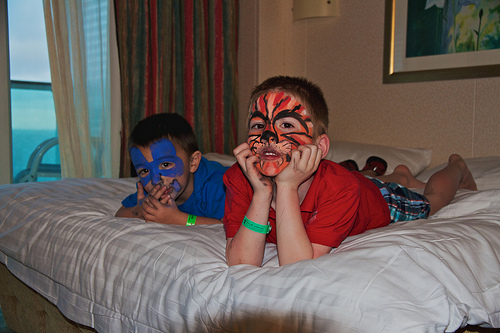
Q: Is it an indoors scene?
A: Yes, it is indoors.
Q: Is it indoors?
A: Yes, it is indoors.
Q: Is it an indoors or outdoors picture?
A: It is indoors.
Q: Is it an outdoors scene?
A: No, it is indoors.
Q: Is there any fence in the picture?
A: No, there are no fences.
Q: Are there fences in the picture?
A: No, there are no fences.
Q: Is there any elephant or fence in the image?
A: No, there are no fences or elephants.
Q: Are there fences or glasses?
A: No, there are no fences or glasses.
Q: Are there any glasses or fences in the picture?
A: No, there are no fences or glasses.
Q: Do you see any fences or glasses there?
A: No, there are no fences or glasses.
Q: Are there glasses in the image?
A: No, there are no glasses.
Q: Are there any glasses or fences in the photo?
A: No, there are no glasses or fences.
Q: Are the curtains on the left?
A: Yes, the curtains are on the left of the image.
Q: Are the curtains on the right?
A: No, the curtains are on the left of the image.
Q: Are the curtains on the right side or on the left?
A: The curtains are on the left of the image.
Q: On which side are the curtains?
A: The curtains are on the left of the image.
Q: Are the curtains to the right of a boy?
A: No, the curtains are to the left of a boy.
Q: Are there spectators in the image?
A: No, there are no spectators.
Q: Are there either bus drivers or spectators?
A: No, there are no spectators or bus drivers.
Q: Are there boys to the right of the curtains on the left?
A: Yes, there is a boy to the right of the curtains.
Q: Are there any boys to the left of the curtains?
A: No, the boy is to the right of the curtains.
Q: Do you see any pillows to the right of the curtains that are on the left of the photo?
A: No, there is a boy to the right of the curtains.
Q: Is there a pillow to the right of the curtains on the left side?
A: No, there is a boy to the right of the curtains.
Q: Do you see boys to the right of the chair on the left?
A: Yes, there is a boy to the right of the chair.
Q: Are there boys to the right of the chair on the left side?
A: Yes, there is a boy to the right of the chair.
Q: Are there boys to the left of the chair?
A: No, the boy is to the right of the chair.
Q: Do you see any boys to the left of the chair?
A: No, the boy is to the right of the chair.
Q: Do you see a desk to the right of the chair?
A: No, there is a boy to the right of the chair.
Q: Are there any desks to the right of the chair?
A: No, there is a boy to the right of the chair.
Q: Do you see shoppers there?
A: No, there are no shoppers.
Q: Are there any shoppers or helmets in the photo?
A: No, there are no shoppers or helmets.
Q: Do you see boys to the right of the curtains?
A: Yes, there is a boy to the right of the curtains.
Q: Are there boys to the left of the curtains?
A: No, the boy is to the right of the curtains.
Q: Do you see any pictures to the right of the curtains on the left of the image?
A: No, there is a boy to the right of the curtains.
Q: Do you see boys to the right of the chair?
A: Yes, there is a boy to the right of the chair.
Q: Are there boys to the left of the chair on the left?
A: No, the boy is to the right of the chair.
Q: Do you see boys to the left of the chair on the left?
A: No, the boy is to the right of the chair.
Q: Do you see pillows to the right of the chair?
A: No, there is a boy to the right of the chair.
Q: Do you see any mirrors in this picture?
A: No, there are no mirrors.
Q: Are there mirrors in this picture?
A: No, there are no mirrors.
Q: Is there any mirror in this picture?
A: No, there are no mirrors.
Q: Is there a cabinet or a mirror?
A: No, there are no mirrors or cabinets.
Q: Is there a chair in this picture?
A: Yes, there is a chair.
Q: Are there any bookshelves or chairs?
A: Yes, there is a chair.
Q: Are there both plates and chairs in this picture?
A: No, there is a chair but no plates.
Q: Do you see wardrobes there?
A: No, there are no wardrobes.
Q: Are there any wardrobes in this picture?
A: No, there are no wardrobes.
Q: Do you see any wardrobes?
A: No, there are no wardrobes.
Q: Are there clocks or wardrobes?
A: No, there are no wardrobes or clocks.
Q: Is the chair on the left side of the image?
A: Yes, the chair is on the left of the image.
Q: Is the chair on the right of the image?
A: No, the chair is on the left of the image.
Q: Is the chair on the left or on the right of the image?
A: The chair is on the left of the image.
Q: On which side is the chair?
A: The chair is on the left of the image.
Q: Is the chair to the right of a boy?
A: No, the chair is to the left of a boy.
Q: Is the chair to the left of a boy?
A: Yes, the chair is to the left of a boy.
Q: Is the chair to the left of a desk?
A: No, the chair is to the left of a boy.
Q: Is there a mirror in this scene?
A: No, there are no mirrors.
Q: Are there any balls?
A: No, there are no balls.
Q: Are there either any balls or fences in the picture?
A: No, there are no balls or fences.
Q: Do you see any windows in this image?
A: Yes, there is a window.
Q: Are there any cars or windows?
A: Yes, there is a window.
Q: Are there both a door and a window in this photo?
A: No, there is a window but no doors.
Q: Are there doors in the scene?
A: No, there are no doors.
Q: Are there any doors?
A: No, there are no doors.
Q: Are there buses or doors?
A: No, there are no doors or buses.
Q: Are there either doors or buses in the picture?
A: No, there are no doors or buses.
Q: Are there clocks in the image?
A: No, there are no clocks.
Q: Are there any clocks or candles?
A: No, there are no clocks or candles.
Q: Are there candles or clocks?
A: No, there are no clocks or candles.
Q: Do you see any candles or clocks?
A: No, there are no clocks or candles.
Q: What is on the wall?
A: The pitcher is on the wall.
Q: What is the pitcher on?
A: The pitcher is on the wall.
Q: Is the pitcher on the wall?
A: Yes, the pitcher is on the wall.